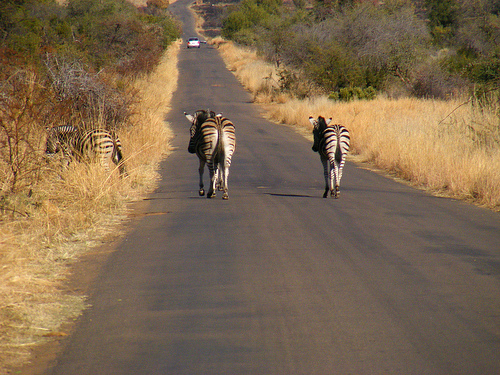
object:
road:
[56, 0, 496, 375]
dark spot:
[256, 185, 267, 189]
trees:
[2, 0, 179, 111]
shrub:
[0, 0, 186, 130]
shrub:
[212, 0, 499, 86]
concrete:
[50, 2, 499, 375]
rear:
[201, 117, 239, 158]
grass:
[0, 39, 178, 370]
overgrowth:
[259, 6, 498, 103]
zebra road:
[4, 110, 149, 182]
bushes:
[326, 85, 377, 104]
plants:
[296, 83, 321, 104]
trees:
[288, 7, 466, 104]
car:
[186, 36, 202, 49]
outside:
[3, 1, 499, 374]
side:
[0, 1, 181, 371]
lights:
[187, 42, 190, 45]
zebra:
[44, 124, 129, 180]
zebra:
[307, 115, 351, 200]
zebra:
[182, 109, 237, 200]